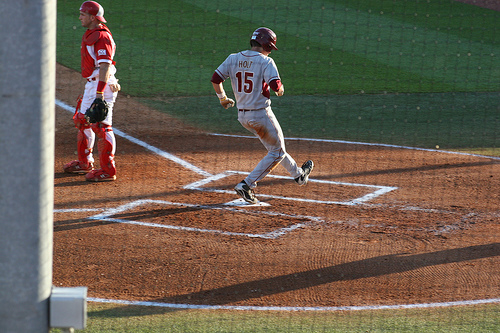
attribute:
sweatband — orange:
[96, 82, 106, 92]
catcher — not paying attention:
[67, 4, 115, 184]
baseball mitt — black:
[86, 97, 107, 127]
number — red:
[231, 70, 255, 96]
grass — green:
[55, 0, 495, 149]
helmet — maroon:
[247, 23, 281, 55]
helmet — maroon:
[71, 1, 117, 25]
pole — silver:
[2, 1, 56, 331]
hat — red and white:
[78, 0, 112, 25]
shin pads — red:
[69, 108, 128, 200]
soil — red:
[53, 128, 497, 330]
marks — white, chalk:
[57, 95, 495, 313]